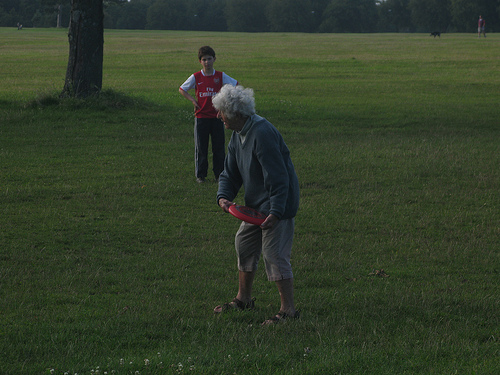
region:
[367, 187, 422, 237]
part of a green ground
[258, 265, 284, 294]
edge of a short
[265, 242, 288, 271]
part of a short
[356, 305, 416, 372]
part of some grass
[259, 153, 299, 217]
part of a sweater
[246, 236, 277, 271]
part of a sweater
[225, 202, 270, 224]
a small red Frisbee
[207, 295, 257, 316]
dark men's sandals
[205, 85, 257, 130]
the head of a man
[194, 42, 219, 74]
the head of a boy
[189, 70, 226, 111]
a boy's red jersey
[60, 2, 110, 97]
the trunk of a tree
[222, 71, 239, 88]
a sleeve of a shirt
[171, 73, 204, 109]
the arm of a boy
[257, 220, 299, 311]
the leg of a man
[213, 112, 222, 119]
the nose of a man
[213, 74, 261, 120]
The white hair of the older person.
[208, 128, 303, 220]
The gray sweater the older person is wearing.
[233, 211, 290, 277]
The capri shorts the older person is wearing.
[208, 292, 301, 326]
The sandals the older person is wearing.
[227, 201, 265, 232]
The red Frisbee the older person is holding.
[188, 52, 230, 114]
The red and white shirt the boy is wearing.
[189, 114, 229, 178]
The black and white pants the boy is wearing.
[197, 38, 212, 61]
The brown hair of the boy.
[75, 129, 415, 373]
The grass area where the older person and boy are playing.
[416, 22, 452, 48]
The dog in the background in front of person.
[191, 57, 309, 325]
a elderly woman holding a frisbee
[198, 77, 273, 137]
a woman with grey hair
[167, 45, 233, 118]
a young boy wearing a red and white shirt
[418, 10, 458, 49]
a black dog walking in a field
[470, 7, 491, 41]
a person walking in a field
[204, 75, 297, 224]
a woman wearing a grey shirt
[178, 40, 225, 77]
a young boy with brown hair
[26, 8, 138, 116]
large tree trunk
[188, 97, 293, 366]
a woman wearing sandles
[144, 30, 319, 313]
a elderly woman and young boy in a field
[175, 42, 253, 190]
boy playing frisbee with his grandmother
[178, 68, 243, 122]
he is wearing a red and white tee shirt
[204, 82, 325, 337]
the woman is wearing a gray sweatshirt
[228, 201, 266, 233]
The woman has a red frisbee in her hand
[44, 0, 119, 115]
tree in park that the boy is playing frisbee in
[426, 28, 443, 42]
black dog running in the park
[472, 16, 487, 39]
owner of the dog running after him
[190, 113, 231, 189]
the boy is wearing blue with white striped jogging pants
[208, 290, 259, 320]
the woman is wearing sandels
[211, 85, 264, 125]
here hair is gray and white